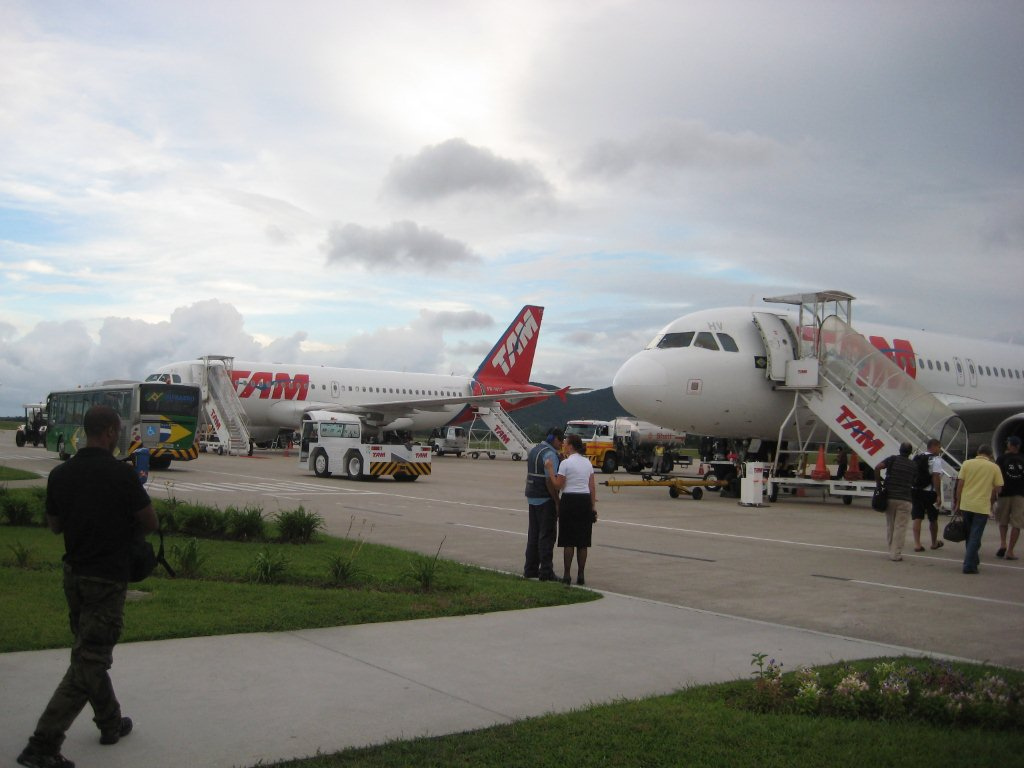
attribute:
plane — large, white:
[561, 218, 996, 594]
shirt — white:
[543, 423, 628, 560]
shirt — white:
[531, 442, 598, 520]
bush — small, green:
[237, 481, 374, 592]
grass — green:
[397, 678, 1000, 763]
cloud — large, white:
[420, 116, 691, 268]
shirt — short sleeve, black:
[41, 454, 193, 582]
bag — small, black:
[930, 493, 963, 548]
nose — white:
[553, 279, 754, 420]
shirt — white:
[531, 420, 637, 496]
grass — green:
[492, 653, 1013, 760]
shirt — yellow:
[946, 451, 1014, 516]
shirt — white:
[557, 449, 605, 486]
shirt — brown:
[877, 449, 925, 506]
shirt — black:
[38, 448, 162, 600]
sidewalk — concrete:
[186, 570, 781, 730]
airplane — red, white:
[125, 295, 568, 456]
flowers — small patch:
[728, 615, 1022, 741]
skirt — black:
[557, 487, 599, 552]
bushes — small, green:
[162, 490, 338, 542]